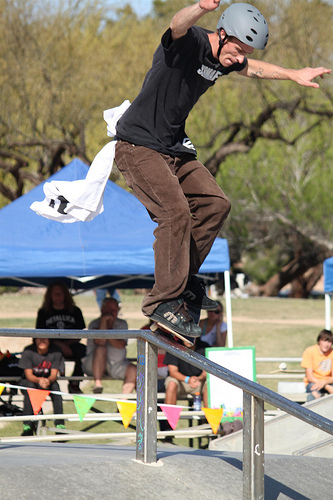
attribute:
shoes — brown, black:
[147, 275, 219, 340]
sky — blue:
[2, 0, 157, 36]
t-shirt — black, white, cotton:
[115, 26, 248, 157]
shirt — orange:
[299, 344, 331, 385]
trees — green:
[0, 0, 332, 297]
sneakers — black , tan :
[108, 280, 206, 337]